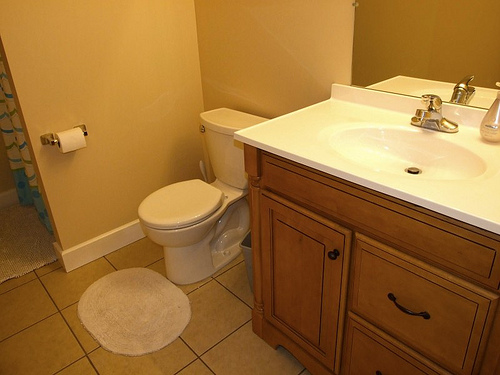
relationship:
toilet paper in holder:
[46, 124, 88, 155] [41, 126, 89, 147]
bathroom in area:
[0, 2, 496, 372] [0, 2, 498, 366]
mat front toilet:
[72, 263, 192, 354] [136, 108, 267, 289]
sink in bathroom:
[231, 94, 498, 231] [0, 2, 496, 372]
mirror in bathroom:
[352, 0, 499, 117] [0, 2, 496, 372]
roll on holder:
[60, 128, 83, 150] [43, 127, 88, 157]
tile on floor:
[6, 249, 302, 371] [1, 211, 283, 363]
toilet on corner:
[136, 108, 267, 289] [123, 27, 242, 265]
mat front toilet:
[72, 263, 192, 354] [82, 71, 273, 297]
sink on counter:
[231, 94, 498, 231] [230, 84, 499, 234]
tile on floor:
[6, 249, 302, 371] [1, 235, 310, 368]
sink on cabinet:
[265, 60, 499, 230] [268, 214, 435, 364]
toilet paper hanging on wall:
[52, 128, 88, 153] [22, 10, 200, 245]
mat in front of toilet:
[72, 259, 209, 366] [136, 108, 267, 289]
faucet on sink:
[411, 94, 458, 133] [231, 94, 498, 231]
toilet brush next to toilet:
[194, 156, 210, 181] [136, 108, 267, 289]